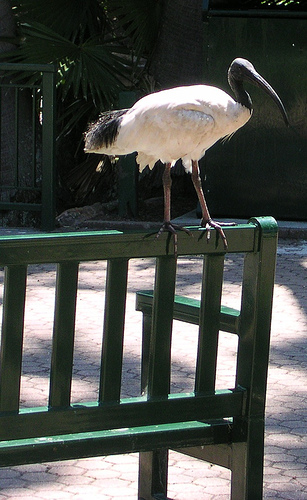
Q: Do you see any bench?
A: Yes, there is a bench.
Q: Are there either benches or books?
A: Yes, there is a bench.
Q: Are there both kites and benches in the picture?
A: No, there is a bench but no kites.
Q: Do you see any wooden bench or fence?
A: Yes, there is a wood bench.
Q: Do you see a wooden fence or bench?
A: Yes, there is a wood bench.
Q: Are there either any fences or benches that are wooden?
A: Yes, the bench is wooden.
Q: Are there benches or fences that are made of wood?
A: Yes, the bench is made of wood.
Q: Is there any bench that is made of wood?
A: Yes, there is a bench that is made of wood.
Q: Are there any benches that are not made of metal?
A: Yes, there is a bench that is made of wood.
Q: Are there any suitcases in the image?
A: No, there are no suitcases.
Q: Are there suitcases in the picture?
A: No, there are no suitcases.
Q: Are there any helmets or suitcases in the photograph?
A: No, there are no suitcases or helmets.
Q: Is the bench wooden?
A: Yes, the bench is wooden.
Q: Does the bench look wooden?
A: Yes, the bench is wooden.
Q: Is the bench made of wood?
A: Yes, the bench is made of wood.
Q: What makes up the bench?
A: The bench is made of wood.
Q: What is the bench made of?
A: The bench is made of wood.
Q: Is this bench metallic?
A: No, the bench is wooden.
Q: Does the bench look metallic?
A: No, the bench is wooden.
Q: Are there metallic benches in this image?
A: No, there is a bench but it is wooden.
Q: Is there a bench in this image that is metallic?
A: No, there is a bench but it is wooden.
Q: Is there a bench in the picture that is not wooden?
A: No, there is a bench but it is wooden.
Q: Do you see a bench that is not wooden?
A: No, there is a bench but it is wooden.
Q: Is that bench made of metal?
A: No, the bench is made of wood.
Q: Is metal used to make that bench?
A: No, the bench is made of wood.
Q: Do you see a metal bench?
A: No, there is a bench but it is made of wood.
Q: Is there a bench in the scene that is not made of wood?
A: No, there is a bench but it is made of wood.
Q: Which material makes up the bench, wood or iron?
A: The bench is made of wood.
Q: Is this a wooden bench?
A: Yes, this is a wooden bench.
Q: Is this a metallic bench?
A: No, this is a wooden bench.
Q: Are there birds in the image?
A: Yes, there is a bird.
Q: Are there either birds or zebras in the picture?
A: Yes, there is a bird.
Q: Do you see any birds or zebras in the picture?
A: Yes, there is a bird.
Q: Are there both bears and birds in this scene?
A: No, there is a bird but no bears.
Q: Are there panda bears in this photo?
A: No, there are no panda bears.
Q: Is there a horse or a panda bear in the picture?
A: No, there are no panda bears or horses.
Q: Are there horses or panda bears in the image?
A: No, there are no panda bears or horses.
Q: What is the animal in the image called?
A: The animal is a bird.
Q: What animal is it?
A: The animal is a bird.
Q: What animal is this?
A: This is a bird.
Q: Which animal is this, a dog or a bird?
A: This is a bird.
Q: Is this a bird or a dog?
A: This is a bird.